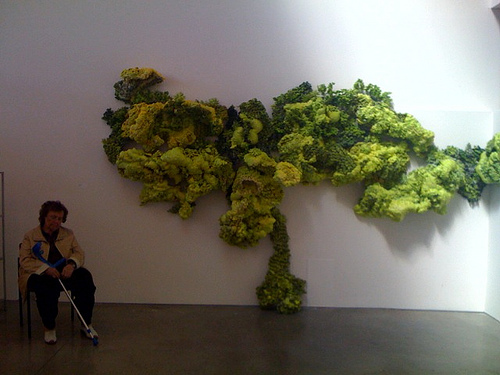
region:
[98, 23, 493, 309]
artwork against white wall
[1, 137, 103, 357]
woman seated in dark corner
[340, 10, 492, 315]
light falling over right side of art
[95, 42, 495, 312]
yellow and green materials used for project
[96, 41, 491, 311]
art is spreading and dropping from wall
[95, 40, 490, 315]
art resembling broccoli florets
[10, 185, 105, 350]
woman slumped down in chair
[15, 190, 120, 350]
metal bar from hand to opposite foot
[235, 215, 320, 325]
artwork touching floor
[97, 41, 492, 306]
art highlighting textures and movement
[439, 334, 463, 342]
part of a floor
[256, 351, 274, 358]
section of a floor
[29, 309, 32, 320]
part of a chair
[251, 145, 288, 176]
a green sculpture on the wall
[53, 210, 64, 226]
face of a woman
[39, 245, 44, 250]
part of a jacket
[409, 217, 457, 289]
part of a white wall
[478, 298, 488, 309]
lower part of a wall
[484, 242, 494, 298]
corner of a wall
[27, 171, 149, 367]
the woman is sleeping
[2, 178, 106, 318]
the woman is sleeping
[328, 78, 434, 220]
this is green kush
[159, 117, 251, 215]
this is green vegetation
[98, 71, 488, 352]
this is a tree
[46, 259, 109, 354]
this is a cane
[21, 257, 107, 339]
these are black pants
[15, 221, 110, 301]
this is a khaki jacket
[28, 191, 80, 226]
these are black curls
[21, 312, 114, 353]
these are white shoes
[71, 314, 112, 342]
this is the left shoe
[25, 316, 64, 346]
this is the right shoe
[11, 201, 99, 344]
A woman sitting in a chair.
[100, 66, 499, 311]
A green decoration against the wall.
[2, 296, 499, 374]
Dark brown floor.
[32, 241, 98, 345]
Blue and silver cane of a woman.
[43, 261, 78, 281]
A woman's hands.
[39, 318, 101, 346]
White sneakers on a woman's feet.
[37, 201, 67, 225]
Dark hair on a mature woman's head.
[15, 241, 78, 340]
A chair that a woman is sitting in.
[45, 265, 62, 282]
Right hand of a woman sitting.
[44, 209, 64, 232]
The face of a woman sitting down.